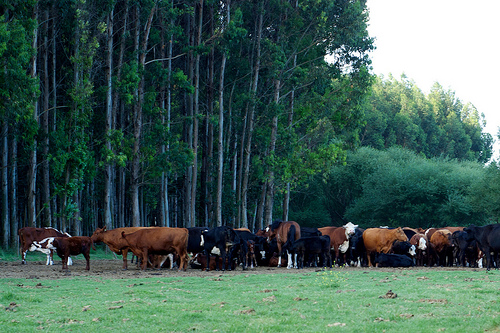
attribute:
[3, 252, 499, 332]
grass — green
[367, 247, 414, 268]
cow — BLACK, LAYING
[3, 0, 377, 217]
trees — tall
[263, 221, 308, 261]
horse — one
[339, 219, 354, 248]
head — white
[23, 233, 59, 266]
calf — WHITE, BROWN SPOTS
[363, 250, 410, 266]
cow — black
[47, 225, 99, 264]
calf — DARK BROWN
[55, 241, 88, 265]
cow — standing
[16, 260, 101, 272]
ground — dried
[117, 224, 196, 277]
cows — BROWN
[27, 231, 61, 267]
cows — brown, white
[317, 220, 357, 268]
cow — BROWN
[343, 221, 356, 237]
face — WHITE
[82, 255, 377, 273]
path — dirt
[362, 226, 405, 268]
cow — light, brown, light brown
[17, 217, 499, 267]
herd — cows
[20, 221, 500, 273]
cows — GROUPED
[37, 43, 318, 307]
trees — GROUPED, TALL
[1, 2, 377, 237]
tree grouping — NARROW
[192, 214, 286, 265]
cow — black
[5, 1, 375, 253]
trees — TALL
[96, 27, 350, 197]
tree — GREEN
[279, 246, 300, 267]
legs — white